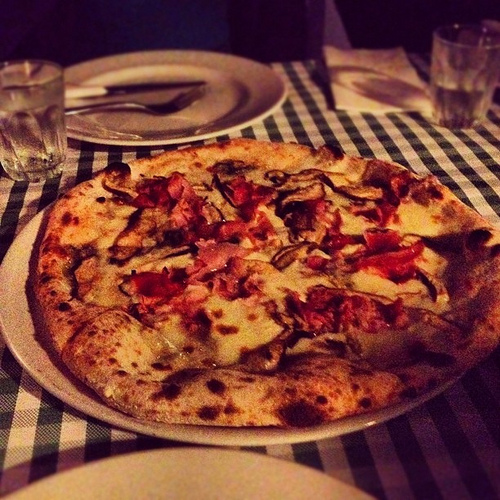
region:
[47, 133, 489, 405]
the pizza on the plate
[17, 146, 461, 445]
the plate is white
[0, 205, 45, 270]
the edge of the plate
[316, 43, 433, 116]
the napkin on the table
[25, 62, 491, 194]
the table cloth is checkered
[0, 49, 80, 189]
the glass on the table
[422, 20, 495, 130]
the glass on the table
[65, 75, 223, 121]
the fork on the plate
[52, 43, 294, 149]
the plate is white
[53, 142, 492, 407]
A delicious looking pizza on a plate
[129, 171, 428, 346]
Different meaty toppings on the pizza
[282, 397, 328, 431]
A small brown burn spot on the pizza crust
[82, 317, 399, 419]
A thick, fluffy pizza crust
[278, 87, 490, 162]
A patterned tablecloth on the table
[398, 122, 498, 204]
Green and white checkered pattern on the tablecloth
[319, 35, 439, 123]
A folded white napkin by the glass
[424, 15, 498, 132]
A half full glass of water by the napkin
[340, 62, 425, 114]
A small black shadow on the white napkin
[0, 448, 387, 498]
A clean white plate next to the pizza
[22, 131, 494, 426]
The pizza pie is round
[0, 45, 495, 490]
A green and white checkered tablecloth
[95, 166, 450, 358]
Cheese on the pizza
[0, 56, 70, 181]
A glass full of water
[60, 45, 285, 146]
Fork and knife on a plate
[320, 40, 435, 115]
A napkin is white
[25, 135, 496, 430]
A crust is around the pizza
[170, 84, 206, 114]
Prongs of a fork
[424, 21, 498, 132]
Glass of water is half full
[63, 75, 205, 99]
Knife has a white handle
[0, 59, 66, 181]
the cup on the table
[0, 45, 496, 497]
the table cloth on the table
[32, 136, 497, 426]
the whole pizza on the plate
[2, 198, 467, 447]
the plate under the food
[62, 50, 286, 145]
the empty plate on the table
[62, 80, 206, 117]
the utensils on the plate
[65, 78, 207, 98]
the knife on the plate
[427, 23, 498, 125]
the cup on the table near the napkin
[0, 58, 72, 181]
A sweaty glass of water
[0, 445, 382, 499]
The rim of a white plate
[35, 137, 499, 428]
A pizza pie with meat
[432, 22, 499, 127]
A half full glass of water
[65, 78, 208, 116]
A shiny set of silverware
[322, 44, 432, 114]
A white paper napkin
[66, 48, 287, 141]
A clean empty white plate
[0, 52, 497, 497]
Green and white checkered table cloth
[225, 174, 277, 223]
Pink fleshy pizza topping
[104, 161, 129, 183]
Black burnt spot on crust